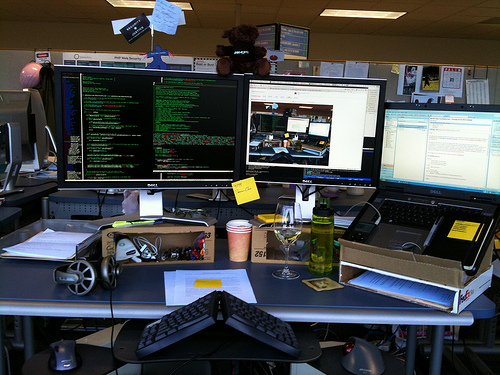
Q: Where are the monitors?
A: In a office.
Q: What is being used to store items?
A: Boxes.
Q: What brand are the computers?
A: Dell.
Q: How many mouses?
A: Two.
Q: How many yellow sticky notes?
A: Three.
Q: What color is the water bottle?
A: Green.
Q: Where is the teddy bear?
A: On top of monitor.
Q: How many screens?
A: Three.